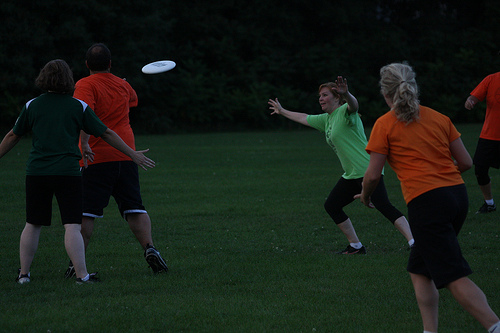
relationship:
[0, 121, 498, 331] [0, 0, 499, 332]
grass at park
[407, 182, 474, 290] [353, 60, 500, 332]
shorts on lady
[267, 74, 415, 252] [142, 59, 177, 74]
woman playing frisbee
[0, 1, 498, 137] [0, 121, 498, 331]
trees on grass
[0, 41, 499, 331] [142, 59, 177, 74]
people playing frisbee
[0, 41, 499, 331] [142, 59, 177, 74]
people trying to catch frisbee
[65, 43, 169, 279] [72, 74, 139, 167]
man wearing a shirt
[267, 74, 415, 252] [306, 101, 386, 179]
woman wearing a shirt